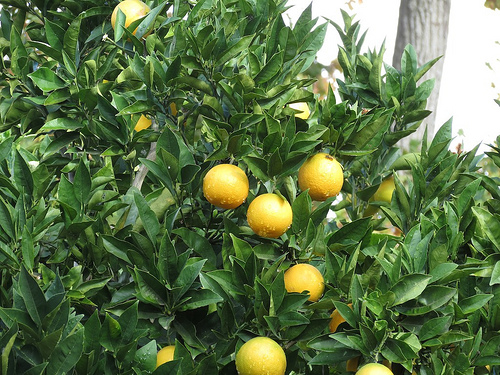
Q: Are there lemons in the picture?
A: Yes, there is a lemon.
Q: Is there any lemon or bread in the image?
A: Yes, there is a lemon.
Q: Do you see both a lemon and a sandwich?
A: No, there is a lemon but no sandwiches.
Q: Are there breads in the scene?
A: No, there are no breads.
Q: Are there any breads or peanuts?
A: No, there are no breads or peanuts.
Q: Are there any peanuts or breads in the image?
A: No, there are no breads or peanuts.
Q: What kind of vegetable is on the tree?
A: The vegetable is a lemon.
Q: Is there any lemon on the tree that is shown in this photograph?
A: Yes, there is a lemon on the tree.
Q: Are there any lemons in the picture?
A: Yes, there is a lemon.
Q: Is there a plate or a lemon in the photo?
A: Yes, there is a lemon.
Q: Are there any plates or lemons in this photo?
A: Yes, there is a lemon.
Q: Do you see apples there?
A: No, there are no apples.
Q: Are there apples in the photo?
A: No, there are no apples.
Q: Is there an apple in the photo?
A: No, there are no apples.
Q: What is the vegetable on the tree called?
A: The vegetable is a lemon.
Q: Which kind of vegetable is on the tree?
A: The vegetable is a lemon.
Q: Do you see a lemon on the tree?
A: Yes, there is a lemon on the tree.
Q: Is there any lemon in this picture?
A: Yes, there is a lemon.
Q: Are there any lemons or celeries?
A: Yes, there is a lemon.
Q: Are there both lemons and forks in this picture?
A: No, there is a lemon but no forks.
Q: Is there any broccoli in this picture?
A: No, there is no broccoli.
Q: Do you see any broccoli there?
A: No, there is no broccoli.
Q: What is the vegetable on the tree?
A: The vegetable is a lemon.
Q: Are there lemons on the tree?
A: Yes, there is a lemon on the tree.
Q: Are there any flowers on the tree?
A: No, there is a lemon on the tree.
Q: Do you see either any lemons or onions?
A: Yes, there is a lemon.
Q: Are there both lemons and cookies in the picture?
A: No, there is a lemon but no cookies.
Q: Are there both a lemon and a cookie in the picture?
A: No, there is a lemon but no cookies.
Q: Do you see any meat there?
A: No, there is no meat.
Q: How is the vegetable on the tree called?
A: The vegetable is a lemon.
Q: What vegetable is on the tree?
A: The vegetable is a lemon.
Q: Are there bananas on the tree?
A: No, there is a lemon on the tree.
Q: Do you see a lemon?
A: Yes, there is a lemon.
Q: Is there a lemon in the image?
A: Yes, there is a lemon.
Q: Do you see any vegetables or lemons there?
A: Yes, there is a lemon.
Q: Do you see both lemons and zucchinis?
A: No, there is a lemon but no zucchinis.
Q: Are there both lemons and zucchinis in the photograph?
A: No, there is a lemon but no zucchinis.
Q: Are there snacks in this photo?
A: No, there are no snacks.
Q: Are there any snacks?
A: No, there are no snacks.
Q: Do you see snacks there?
A: No, there are no snacks.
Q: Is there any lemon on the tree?
A: Yes, there is a lemon on the tree.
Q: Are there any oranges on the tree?
A: No, there is a lemon on the tree.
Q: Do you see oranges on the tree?
A: No, there is a lemon on the tree.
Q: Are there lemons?
A: Yes, there are lemons.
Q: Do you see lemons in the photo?
A: Yes, there are lemons.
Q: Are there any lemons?
A: Yes, there are lemons.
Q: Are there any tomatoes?
A: No, there are no tomatoes.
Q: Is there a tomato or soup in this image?
A: No, there are no tomatoes or soup.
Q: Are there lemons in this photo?
A: Yes, there are lemons.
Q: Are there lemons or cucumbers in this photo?
A: Yes, there are lemons.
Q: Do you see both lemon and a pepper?
A: No, there are lemons but no peppers.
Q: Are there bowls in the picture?
A: No, there are no bowls.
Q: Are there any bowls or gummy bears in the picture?
A: No, there are no bowls or gummy bears.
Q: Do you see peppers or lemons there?
A: Yes, there are lemons.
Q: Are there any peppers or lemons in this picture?
A: Yes, there are lemons.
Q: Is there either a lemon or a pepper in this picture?
A: Yes, there are lemons.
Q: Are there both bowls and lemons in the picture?
A: No, there are lemons but no bowls.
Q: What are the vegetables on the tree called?
A: The vegetables are lemons.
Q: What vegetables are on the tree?
A: The vegetables are lemons.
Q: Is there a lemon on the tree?
A: Yes, there are lemons on the tree.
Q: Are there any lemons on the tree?
A: Yes, there are lemons on the tree.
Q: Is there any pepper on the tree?
A: No, there are lemons on the tree.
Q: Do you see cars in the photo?
A: No, there are no cars.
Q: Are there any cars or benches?
A: No, there are no cars or benches.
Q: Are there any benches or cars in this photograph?
A: No, there are no cars or benches.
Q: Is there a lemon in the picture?
A: Yes, there are lemons.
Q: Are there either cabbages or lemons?
A: Yes, there are lemons.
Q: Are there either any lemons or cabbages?
A: Yes, there are lemons.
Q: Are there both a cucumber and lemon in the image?
A: No, there are lemons but no cucumbers.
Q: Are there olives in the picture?
A: No, there are no olives.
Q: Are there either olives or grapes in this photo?
A: No, there are no olives or grapes.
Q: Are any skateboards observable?
A: No, there are no skateboards.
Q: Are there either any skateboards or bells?
A: No, there are no skateboards or bells.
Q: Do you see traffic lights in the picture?
A: No, there are no traffic lights.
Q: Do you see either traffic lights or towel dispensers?
A: No, there are no traffic lights or towel dispensers.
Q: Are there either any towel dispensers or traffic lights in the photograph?
A: No, there are no traffic lights or towel dispensers.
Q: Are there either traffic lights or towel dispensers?
A: No, there are no traffic lights or towel dispensers.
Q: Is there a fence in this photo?
A: No, there are no fences.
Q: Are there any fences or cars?
A: No, there are no fences or cars.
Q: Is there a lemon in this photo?
A: Yes, there are lemons.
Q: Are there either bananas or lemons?
A: Yes, there are lemons.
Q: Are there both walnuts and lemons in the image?
A: No, there are lemons but no walnuts.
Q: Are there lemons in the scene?
A: Yes, there are lemons.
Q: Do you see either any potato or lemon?
A: Yes, there are lemons.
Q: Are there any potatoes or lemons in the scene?
A: Yes, there are lemons.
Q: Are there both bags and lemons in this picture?
A: No, there are lemons but no bags.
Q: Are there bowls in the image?
A: No, there are no bowls.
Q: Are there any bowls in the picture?
A: No, there are no bowls.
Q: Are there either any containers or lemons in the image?
A: Yes, there are lemons.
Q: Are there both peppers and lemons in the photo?
A: No, there are lemons but no peppers.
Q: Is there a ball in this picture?
A: No, there are no balls.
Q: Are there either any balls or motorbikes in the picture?
A: No, there are no balls or motorbikes.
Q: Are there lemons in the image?
A: Yes, there are lemons.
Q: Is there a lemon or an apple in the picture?
A: Yes, there are lemons.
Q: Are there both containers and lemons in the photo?
A: No, there are lemons but no containers.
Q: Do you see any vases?
A: No, there are no vases.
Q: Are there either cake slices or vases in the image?
A: No, there are no vases or cake slices.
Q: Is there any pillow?
A: No, there are no pillows.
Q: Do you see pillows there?
A: No, there are no pillows.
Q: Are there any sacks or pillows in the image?
A: No, there are no pillows or sacks.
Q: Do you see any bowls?
A: No, there are no bowls.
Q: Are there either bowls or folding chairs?
A: No, there are no bowls or folding chairs.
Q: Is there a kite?
A: No, there are no kites.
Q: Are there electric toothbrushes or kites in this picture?
A: No, there are no kites or electric toothbrushes.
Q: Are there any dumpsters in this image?
A: No, there are no dumpsters.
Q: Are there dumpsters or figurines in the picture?
A: No, there are no dumpsters or figurines.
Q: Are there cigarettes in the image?
A: No, there are no cigarettes.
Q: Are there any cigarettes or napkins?
A: No, there are no cigarettes or napkins.